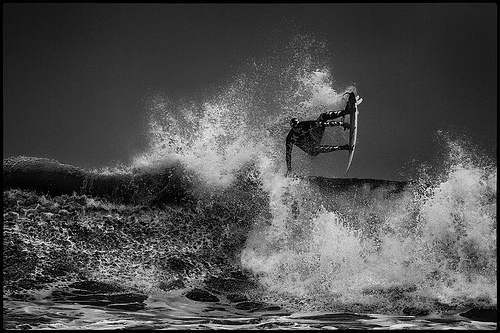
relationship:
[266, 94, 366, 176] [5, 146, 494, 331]
surfer on top of waves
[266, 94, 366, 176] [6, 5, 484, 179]
surfer in air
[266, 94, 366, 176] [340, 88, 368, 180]
surfer connected to surfboard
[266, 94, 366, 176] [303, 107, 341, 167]
surfer wearing wet suit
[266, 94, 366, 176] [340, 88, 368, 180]
surfer riding surfboard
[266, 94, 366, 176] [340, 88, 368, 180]
surfer doing trick on surfboard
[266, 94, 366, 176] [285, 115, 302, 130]
surfer wearing a helmet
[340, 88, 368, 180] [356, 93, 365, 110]
surfboard has fins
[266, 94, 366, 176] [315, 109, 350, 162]
surfer has legs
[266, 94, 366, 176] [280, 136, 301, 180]
surfer has arm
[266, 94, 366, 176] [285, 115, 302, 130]
surfer has helmet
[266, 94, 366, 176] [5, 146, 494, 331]
surfer above waves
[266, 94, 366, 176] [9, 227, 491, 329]
surfer above ocean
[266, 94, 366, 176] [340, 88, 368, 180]
surfer on top of surfboard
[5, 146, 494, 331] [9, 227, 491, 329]
waves are above ocean